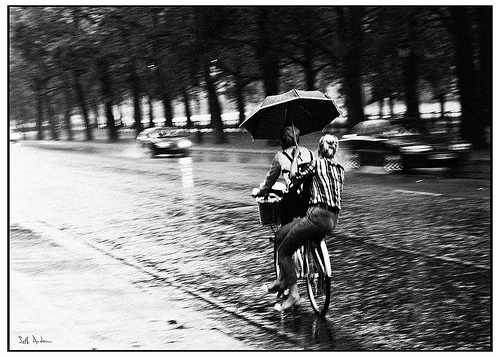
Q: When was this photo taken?
A: During the daytime.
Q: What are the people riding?
A: A bicycle.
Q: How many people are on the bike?
A: Two.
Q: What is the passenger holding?
A: An umbrella.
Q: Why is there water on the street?
A: It's raining.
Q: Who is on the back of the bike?
A: A woman.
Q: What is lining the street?
A: Trees.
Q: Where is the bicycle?
A: On the street.